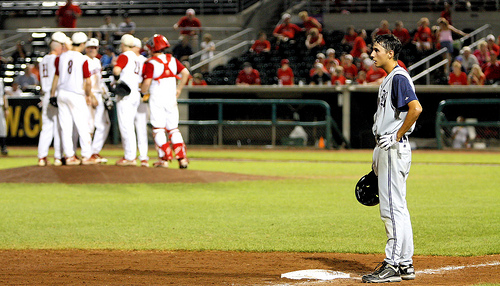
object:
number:
[63, 58, 75, 76]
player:
[360, 34, 417, 284]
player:
[135, 29, 196, 168]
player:
[110, 30, 142, 167]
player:
[53, 32, 102, 163]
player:
[35, 37, 70, 163]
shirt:
[53, 48, 90, 95]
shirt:
[370, 65, 417, 135]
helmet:
[141, 29, 173, 61]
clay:
[4, 245, 499, 283]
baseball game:
[6, 3, 436, 284]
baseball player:
[113, 37, 153, 164]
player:
[344, 21, 459, 283]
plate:
[280, 263, 357, 283]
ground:
[1, 140, 498, 282]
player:
[57, 34, 94, 164]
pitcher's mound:
[1, 163, 288, 184]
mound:
[0, 159, 292, 187]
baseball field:
[2, 142, 498, 280]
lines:
[351, 257, 498, 277]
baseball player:
[351, 33, 481, 254]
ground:
[367, 122, 423, 166]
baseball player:
[47, 28, 102, 168]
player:
[144, 39, 193, 167]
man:
[142, 30, 190, 169]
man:
[113, 33, 138, 162]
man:
[55, 30, 97, 167]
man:
[35, 27, 65, 169]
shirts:
[344, 58, 435, 137]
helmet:
[344, 160, 386, 226]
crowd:
[177, 1, 497, 91]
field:
[24, 18, 499, 262]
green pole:
[178, 94, 331, 109]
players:
[30, 23, 210, 135]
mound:
[0, 116, 232, 230]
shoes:
[360, 258, 400, 284]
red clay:
[2, 245, 499, 281]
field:
[6, 148, 498, 284]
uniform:
[375, 64, 420, 280]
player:
[368, 39, 420, 282]